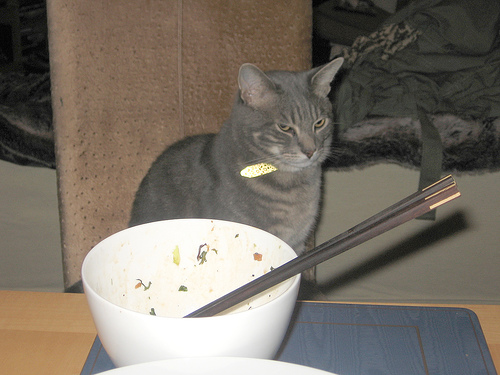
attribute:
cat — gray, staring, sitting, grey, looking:
[230, 69, 339, 199]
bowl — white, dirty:
[103, 227, 273, 330]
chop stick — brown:
[345, 182, 446, 234]